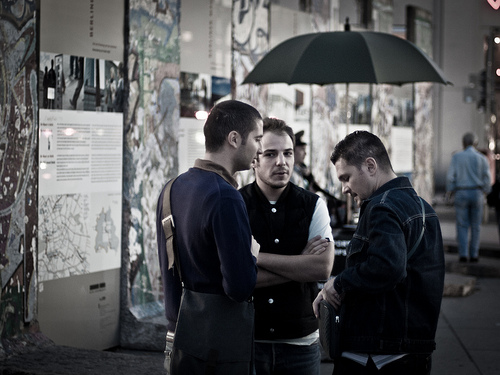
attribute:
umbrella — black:
[242, 24, 469, 91]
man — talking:
[161, 65, 263, 359]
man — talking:
[258, 114, 334, 369]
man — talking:
[332, 130, 450, 374]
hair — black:
[202, 89, 262, 148]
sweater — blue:
[146, 167, 258, 299]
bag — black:
[297, 278, 358, 367]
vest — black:
[238, 182, 316, 259]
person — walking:
[441, 130, 493, 266]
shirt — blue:
[444, 150, 493, 191]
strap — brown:
[148, 180, 201, 281]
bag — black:
[170, 286, 257, 361]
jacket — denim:
[336, 187, 455, 348]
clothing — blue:
[442, 144, 495, 266]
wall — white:
[6, 3, 152, 362]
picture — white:
[27, 105, 134, 276]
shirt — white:
[296, 194, 342, 245]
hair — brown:
[332, 127, 400, 169]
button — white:
[267, 205, 282, 217]